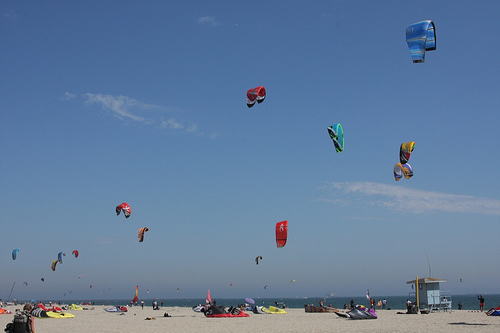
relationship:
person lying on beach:
[23, 303, 67, 320] [2, 299, 497, 333]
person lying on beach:
[204, 305, 241, 315] [2, 299, 497, 333]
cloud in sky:
[63, 88, 217, 141] [1, 3, 499, 299]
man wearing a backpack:
[5, 303, 37, 330] [12, 312, 31, 332]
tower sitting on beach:
[406, 276, 452, 315] [2, 299, 497, 333]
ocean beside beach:
[5, 298, 499, 312] [2, 299, 497, 333]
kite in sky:
[391, 139, 417, 182] [1, 3, 499, 299]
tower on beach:
[406, 276, 452, 315] [2, 299, 497, 333]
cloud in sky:
[319, 179, 499, 216] [1, 3, 499, 299]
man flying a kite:
[475, 292, 486, 311] [459, 279, 464, 284]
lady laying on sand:
[22, 304, 61, 320] [2, 305, 499, 333]